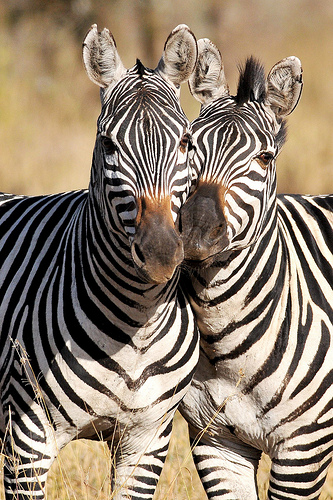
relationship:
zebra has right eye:
[0, 21, 196, 498] [179, 132, 190, 147]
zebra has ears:
[0, 21, 196, 498] [81, 24, 198, 92]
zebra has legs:
[0, 21, 196, 498] [0, 423, 168, 499]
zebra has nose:
[0, 21, 196, 498] [136, 218, 187, 286]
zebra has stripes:
[0, 21, 196, 498] [4, 65, 197, 498]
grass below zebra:
[64, 447, 192, 498] [0, 21, 196, 498]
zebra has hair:
[183, 32, 332, 490] [239, 57, 270, 104]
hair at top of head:
[239, 57, 270, 104] [175, 88, 278, 273]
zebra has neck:
[0, 21, 196, 498] [92, 208, 166, 326]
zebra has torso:
[0, 21, 196, 498] [36, 319, 190, 453]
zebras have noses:
[0, 23, 331, 496] [127, 188, 233, 282]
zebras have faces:
[0, 23, 331, 496] [94, 67, 283, 283]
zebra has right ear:
[0, 21, 196, 498] [159, 26, 203, 81]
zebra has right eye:
[0, 21, 196, 498] [179, 138, 193, 158]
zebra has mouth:
[0, 21, 196, 498] [129, 242, 182, 289]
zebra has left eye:
[0, 21, 196, 498] [97, 134, 122, 154]